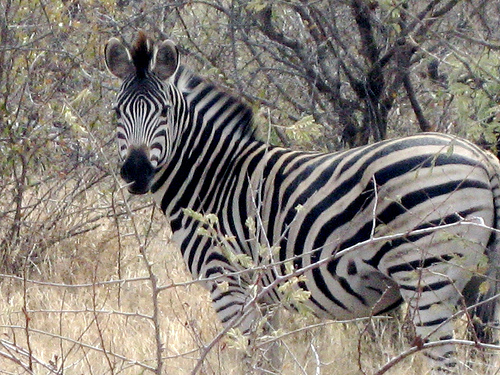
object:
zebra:
[104, 30, 500, 375]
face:
[114, 87, 175, 194]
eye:
[111, 108, 121, 120]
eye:
[161, 105, 170, 116]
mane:
[129, 29, 264, 138]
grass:
[1, 182, 500, 375]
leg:
[400, 264, 469, 375]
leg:
[475, 253, 498, 352]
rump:
[440, 135, 500, 277]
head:
[102, 38, 188, 194]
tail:
[488, 165, 500, 243]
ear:
[101, 37, 136, 81]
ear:
[150, 39, 181, 81]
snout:
[118, 152, 156, 195]